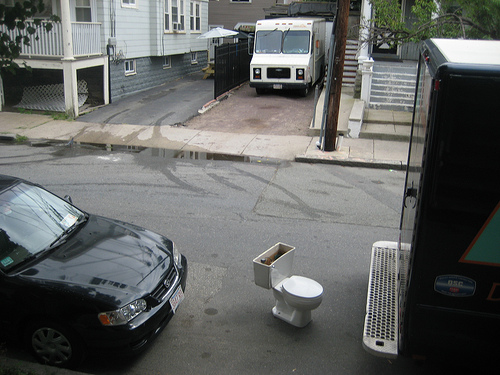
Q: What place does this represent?
A: It represents the street.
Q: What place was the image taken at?
A: It was taken at the street.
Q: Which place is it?
A: It is a street.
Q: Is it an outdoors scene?
A: Yes, it is outdoors.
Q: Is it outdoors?
A: Yes, it is outdoors.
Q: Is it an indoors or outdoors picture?
A: It is outdoors.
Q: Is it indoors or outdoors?
A: It is outdoors.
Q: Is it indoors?
A: No, it is outdoors.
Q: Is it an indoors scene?
A: No, it is outdoors.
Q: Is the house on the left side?
A: Yes, the house is on the left of the image.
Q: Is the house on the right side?
A: No, the house is on the left of the image.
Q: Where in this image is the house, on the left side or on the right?
A: The house is on the left of the image.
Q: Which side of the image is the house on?
A: The house is on the left of the image.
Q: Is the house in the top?
A: Yes, the house is in the top of the image.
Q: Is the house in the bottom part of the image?
A: No, the house is in the top of the image.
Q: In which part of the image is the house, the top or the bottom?
A: The house is in the top of the image.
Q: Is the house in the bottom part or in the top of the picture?
A: The house is in the top of the image.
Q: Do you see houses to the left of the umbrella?
A: Yes, there is a house to the left of the umbrella.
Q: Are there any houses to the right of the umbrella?
A: No, the house is to the left of the umbrella.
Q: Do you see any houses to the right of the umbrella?
A: No, the house is to the left of the umbrella.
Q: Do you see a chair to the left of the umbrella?
A: No, there is a house to the left of the umbrella.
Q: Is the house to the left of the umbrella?
A: Yes, the house is to the left of the umbrella.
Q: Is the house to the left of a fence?
A: No, the house is to the left of the umbrella.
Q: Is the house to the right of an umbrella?
A: No, the house is to the left of an umbrella.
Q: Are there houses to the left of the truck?
A: Yes, there is a house to the left of the truck.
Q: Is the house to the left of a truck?
A: Yes, the house is to the left of a truck.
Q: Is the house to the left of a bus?
A: No, the house is to the left of a truck.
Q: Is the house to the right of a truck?
A: No, the house is to the left of a truck.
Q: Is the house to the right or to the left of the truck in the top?
A: The house is to the left of the truck.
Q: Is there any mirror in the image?
A: No, there are no mirrors.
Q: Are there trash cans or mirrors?
A: No, there are no mirrors or trash cans.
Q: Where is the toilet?
A: The toilet is on the street.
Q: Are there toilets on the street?
A: Yes, there is a toilet on the street.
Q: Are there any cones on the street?
A: No, there is a toilet on the street.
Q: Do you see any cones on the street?
A: No, there is a toilet on the street.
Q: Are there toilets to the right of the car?
A: Yes, there is a toilet to the right of the car.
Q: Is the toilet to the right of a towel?
A: No, the toilet is to the right of the car.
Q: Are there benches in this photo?
A: No, there are no benches.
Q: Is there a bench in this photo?
A: No, there are no benches.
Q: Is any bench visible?
A: No, there are no benches.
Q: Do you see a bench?
A: No, there are no benches.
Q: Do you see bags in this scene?
A: No, there are no bags.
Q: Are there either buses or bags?
A: No, there are no bags or buses.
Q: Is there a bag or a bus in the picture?
A: No, there are no bags or buses.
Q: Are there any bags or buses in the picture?
A: No, there are no bags or buses.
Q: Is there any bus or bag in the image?
A: No, there are no bags or buses.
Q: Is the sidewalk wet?
A: Yes, the sidewalk is wet.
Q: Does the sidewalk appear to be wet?
A: Yes, the sidewalk is wet.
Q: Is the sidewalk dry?
A: No, the sidewalk is wet.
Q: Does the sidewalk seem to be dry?
A: No, the sidewalk is wet.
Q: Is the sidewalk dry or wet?
A: The sidewalk is wet.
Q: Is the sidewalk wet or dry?
A: The sidewalk is wet.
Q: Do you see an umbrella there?
A: Yes, there is an umbrella.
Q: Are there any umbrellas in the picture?
A: Yes, there is an umbrella.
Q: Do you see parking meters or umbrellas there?
A: Yes, there is an umbrella.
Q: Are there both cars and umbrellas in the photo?
A: Yes, there are both an umbrella and a car.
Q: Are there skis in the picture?
A: No, there are no skis.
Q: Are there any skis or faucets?
A: No, there are no skis or faucets.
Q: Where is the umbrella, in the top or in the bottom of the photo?
A: The umbrella is in the top of the image.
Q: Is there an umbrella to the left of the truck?
A: Yes, there is an umbrella to the left of the truck.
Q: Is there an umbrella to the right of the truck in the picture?
A: No, the umbrella is to the left of the truck.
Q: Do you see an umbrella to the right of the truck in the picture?
A: No, the umbrella is to the left of the truck.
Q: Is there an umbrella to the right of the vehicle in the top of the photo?
A: No, the umbrella is to the left of the truck.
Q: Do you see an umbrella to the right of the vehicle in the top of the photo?
A: No, the umbrella is to the left of the truck.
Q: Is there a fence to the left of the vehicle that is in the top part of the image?
A: No, there is an umbrella to the left of the truck.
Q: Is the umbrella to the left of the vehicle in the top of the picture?
A: Yes, the umbrella is to the left of the truck.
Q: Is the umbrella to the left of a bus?
A: No, the umbrella is to the left of the truck.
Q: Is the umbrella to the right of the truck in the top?
A: No, the umbrella is to the left of the truck.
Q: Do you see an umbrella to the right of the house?
A: Yes, there is an umbrella to the right of the house.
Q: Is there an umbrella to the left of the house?
A: No, the umbrella is to the right of the house.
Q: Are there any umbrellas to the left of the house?
A: No, the umbrella is to the right of the house.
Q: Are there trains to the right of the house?
A: No, there is an umbrella to the right of the house.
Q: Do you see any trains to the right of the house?
A: No, there is an umbrella to the right of the house.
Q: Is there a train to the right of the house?
A: No, there is an umbrella to the right of the house.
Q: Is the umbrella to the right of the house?
A: Yes, the umbrella is to the right of the house.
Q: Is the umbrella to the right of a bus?
A: No, the umbrella is to the right of the house.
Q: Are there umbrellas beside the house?
A: Yes, there is an umbrella beside the house.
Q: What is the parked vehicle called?
A: The vehicle is a car.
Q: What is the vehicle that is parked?
A: The vehicle is a car.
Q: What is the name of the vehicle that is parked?
A: The vehicle is a car.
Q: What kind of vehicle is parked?
A: The vehicle is a car.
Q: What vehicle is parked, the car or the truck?
A: The car is parked.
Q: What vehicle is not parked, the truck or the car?
A: The truck is not parked.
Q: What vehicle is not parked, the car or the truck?
A: The truck is not parked.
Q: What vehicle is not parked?
A: The vehicle is a truck.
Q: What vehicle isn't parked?
A: The vehicle is a truck.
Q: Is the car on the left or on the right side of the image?
A: The car is on the left of the image.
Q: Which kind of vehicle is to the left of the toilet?
A: The vehicle is a car.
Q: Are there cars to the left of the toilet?
A: Yes, there is a car to the left of the toilet.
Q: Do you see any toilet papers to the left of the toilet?
A: No, there is a car to the left of the toilet.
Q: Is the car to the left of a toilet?
A: Yes, the car is to the left of a toilet.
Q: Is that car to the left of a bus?
A: No, the car is to the left of a toilet.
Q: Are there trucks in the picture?
A: Yes, there is a truck.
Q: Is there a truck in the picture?
A: Yes, there is a truck.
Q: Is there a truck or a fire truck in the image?
A: Yes, there is a truck.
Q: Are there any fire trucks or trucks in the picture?
A: Yes, there is a truck.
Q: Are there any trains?
A: No, there are no trains.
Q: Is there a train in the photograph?
A: No, there are no trains.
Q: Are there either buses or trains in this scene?
A: No, there are no trains or buses.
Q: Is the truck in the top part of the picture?
A: Yes, the truck is in the top of the image.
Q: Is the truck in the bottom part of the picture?
A: No, the truck is in the top of the image.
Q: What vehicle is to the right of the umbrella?
A: The vehicle is a truck.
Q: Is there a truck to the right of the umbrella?
A: Yes, there is a truck to the right of the umbrella.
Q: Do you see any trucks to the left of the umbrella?
A: No, the truck is to the right of the umbrella.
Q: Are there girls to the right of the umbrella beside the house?
A: No, there is a truck to the right of the umbrella.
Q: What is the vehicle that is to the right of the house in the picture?
A: The vehicle is a truck.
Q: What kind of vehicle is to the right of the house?
A: The vehicle is a truck.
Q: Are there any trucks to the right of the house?
A: Yes, there is a truck to the right of the house.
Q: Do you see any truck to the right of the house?
A: Yes, there is a truck to the right of the house.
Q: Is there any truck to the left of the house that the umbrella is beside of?
A: No, the truck is to the right of the house.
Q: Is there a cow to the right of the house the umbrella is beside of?
A: No, there is a truck to the right of the house.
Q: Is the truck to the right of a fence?
A: No, the truck is to the right of the house.